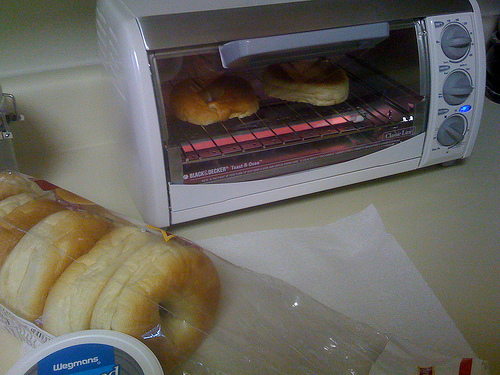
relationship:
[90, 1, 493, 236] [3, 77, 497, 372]
toaster oven on counter top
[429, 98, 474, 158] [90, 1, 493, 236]
timer on toaster oven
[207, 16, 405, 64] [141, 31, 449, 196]
handle on door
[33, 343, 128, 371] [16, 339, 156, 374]
wegmans on label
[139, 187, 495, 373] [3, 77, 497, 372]
paper on counter top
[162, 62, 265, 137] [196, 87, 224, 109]
bagel containing hole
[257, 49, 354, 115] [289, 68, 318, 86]
bagel containing hole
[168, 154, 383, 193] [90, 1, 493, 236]
label on toaster oven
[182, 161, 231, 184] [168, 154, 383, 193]
black and decker on label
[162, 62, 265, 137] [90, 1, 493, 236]
bagel in toaster oven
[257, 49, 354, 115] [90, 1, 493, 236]
bagel in toaster oven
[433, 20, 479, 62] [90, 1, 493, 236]
knob on toaster oven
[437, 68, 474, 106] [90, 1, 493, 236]
knob on toaster oven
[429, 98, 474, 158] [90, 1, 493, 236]
knob on toaster oven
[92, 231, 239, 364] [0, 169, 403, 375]
bagel inside bag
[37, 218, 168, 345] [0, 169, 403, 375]
bagel inside bag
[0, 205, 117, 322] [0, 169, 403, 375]
bagel inside bag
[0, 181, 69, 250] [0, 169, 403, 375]
bagel inside bag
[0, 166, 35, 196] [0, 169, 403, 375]
bagel inside bag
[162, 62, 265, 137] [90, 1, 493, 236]
bagel inside oven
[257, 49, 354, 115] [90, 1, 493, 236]
bagel inside oven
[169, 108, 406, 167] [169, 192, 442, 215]
light on bottom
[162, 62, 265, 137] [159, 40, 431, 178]
bagel on rack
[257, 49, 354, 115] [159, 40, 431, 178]
bagel on rack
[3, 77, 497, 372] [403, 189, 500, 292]
surface has part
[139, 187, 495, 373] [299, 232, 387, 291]
polythene has part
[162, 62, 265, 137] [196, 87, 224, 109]
doughnut contains hole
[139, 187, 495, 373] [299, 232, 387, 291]
paper has part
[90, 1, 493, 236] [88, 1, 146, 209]
microwave has edge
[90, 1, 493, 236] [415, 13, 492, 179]
microwave has part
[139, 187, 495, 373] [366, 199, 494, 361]
tissue has edge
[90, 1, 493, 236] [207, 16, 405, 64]
microwave has part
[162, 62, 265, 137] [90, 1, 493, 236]
bagel top inside oven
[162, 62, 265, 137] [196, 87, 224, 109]
bagel contains hole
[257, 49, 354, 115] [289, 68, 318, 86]
bagel contains hole